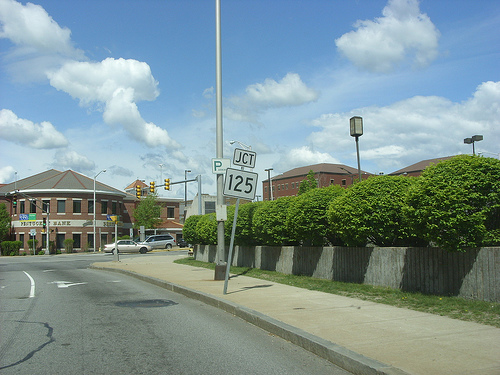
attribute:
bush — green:
[405, 154, 499, 249]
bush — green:
[324, 175, 411, 247]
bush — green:
[282, 184, 341, 241]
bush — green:
[248, 194, 297, 247]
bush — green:
[195, 215, 221, 246]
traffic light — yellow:
[133, 181, 144, 203]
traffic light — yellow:
[147, 178, 157, 197]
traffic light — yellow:
[162, 175, 173, 192]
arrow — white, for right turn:
[48, 277, 88, 290]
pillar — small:
[222, 197, 241, 294]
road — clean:
[1, 252, 357, 374]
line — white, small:
[19, 267, 39, 301]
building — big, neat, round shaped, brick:
[3, 168, 183, 256]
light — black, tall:
[348, 114, 367, 182]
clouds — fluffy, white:
[7, 5, 186, 172]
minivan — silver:
[138, 233, 177, 250]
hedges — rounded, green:
[175, 156, 500, 250]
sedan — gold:
[101, 236, 151, 255]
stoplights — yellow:
[134, 176, 176, 198]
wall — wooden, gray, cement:
[190, 240, 499, 308]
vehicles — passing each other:
[102, 228, 177, 255]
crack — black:
[3, 316, 58, 373]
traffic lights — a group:
[132, 179, 172, 198]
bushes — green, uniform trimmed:
[184, 147, 499, 249]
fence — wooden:
[189, 242, 499, 308]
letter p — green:
[212, 157, 224, 174]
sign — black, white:
[224, 166, 259, 200]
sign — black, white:
[233, 147, 258, 168]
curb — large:
[102, 264, 295, 374]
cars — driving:
[103, 230, 177, 258]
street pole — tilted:
[216, 199, 242, 298]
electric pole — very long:
[209, 1, 235, 280]